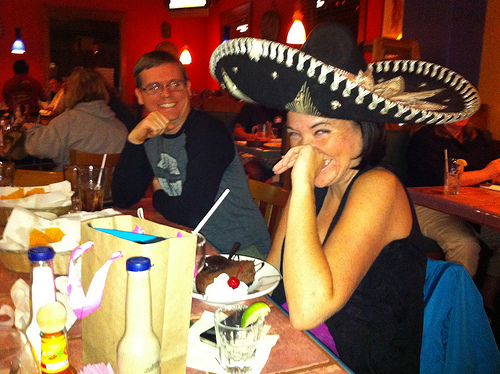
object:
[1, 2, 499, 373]
restaurant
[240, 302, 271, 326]
lime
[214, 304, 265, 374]
glass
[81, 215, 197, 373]
bag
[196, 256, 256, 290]
cake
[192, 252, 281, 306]
plate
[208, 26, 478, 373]
woman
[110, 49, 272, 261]
man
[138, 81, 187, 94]
glasses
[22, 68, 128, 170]
person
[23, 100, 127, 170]
hoodie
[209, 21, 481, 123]
sombrero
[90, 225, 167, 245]
gift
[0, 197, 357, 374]
table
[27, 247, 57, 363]
salt shaker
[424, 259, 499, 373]
windbreaker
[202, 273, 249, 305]
whipped cream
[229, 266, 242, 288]
cherry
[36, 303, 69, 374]
bottle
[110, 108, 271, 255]
shirt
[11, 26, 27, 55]
lamp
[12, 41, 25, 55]
shade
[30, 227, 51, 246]
tortilla chip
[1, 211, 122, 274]
basket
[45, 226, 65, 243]
tortilla chip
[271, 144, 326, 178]
hand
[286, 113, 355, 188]
face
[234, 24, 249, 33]
light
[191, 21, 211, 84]
wall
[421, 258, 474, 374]
chair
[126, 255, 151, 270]
lid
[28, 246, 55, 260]
lid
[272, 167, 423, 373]
dress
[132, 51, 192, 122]
head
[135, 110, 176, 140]
hand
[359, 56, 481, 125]
trim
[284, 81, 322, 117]
embroidery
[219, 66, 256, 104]
embroidery